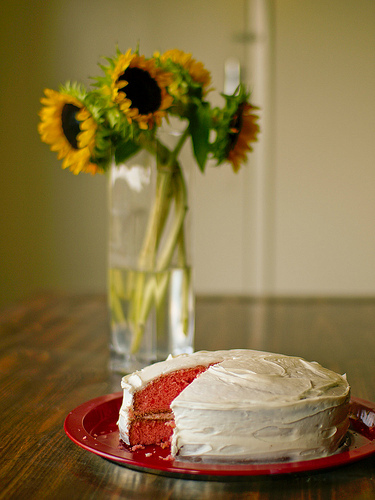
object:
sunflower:
[36, 79, 109, 177]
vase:
[106, 130, 201, 375]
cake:
[118, 349, 352, 464]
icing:
[118, 349, 351, 462]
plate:
[63, 392, 374, 479]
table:
[2, 290, 374, 500]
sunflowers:
[215, 83, 260, 173]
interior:
[131, 363, 220, 446]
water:
[103, 256, 197, 366]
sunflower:
[110, 48, 193, 357]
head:
[107, 47, 174, 121]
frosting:
[140, 412, 175, 423]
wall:
[0, 0, 373, 299]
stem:
[147, 130, 189, 253]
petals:
[37, 86, 90, 175]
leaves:
[113, 137, 142, 164]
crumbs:
[144, 451, 154, 456]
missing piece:
[132, 362, 218, 461]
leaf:
[186, 97, 213, 172]